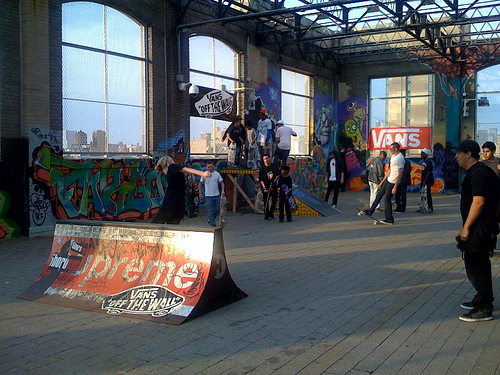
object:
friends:
[145, 111, 453, 232]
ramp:
[12, 215, 254, 328]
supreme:
[37, 238, 199, 292]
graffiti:
[16, 76, 464, 242]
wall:
[1, 1, 499, 228]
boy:
[193, 159, 229, 227]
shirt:
[201, 169, 224, 198]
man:
[444, 137, 498, 323]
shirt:
[458, 162, 499, 236]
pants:
[453, 231, 495, 311]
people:
[140, 106, 498, 324]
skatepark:
[1, 182, 499, 374]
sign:
[361, 125, 434, 152]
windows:
[53, 2, 158, 160]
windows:
[175, 32, 251, 163]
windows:
[363, 73, 440, 131]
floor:
[2, 216, 500, 374]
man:
[352, 140, 413, 228]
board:
[350, 203, 399, 229]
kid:
[272, 164, 299, 224]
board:
[281, 179, 348, 221]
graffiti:
[47, 230, 210, 324]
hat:
[445, 134, 483, 161]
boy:
[272, 161, 304, 227]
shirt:
[159, 164, 192, 202]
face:
[309, 105, 337, 146]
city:
[63, 23, 229, 160]